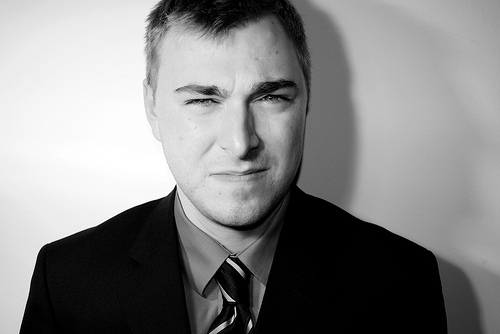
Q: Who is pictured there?
A: Young man.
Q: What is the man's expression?
A: Grimace.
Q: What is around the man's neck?
A: Tie.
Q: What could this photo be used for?
A: Headshot.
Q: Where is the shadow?
A: Wall.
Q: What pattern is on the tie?
A: Stripes.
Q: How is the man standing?
A: Posing.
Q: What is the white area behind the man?
A: The wall.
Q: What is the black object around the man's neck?
A: A tie.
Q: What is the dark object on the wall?
A: A shadow.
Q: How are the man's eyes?
A: Squinting.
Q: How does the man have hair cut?
A: Short.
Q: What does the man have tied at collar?
A: Tie.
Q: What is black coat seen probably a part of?
A: Suit.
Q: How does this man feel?
A: Unhappy.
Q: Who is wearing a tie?
A: The man.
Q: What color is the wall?
A: White.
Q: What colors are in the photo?
A: Black and white.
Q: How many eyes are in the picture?
A: Two.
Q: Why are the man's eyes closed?
A: Bright light.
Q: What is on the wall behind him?
A: Shadow.